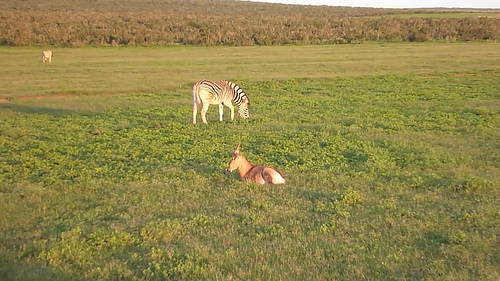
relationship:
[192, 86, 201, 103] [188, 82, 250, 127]
tail on zebra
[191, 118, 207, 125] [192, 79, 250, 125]
feet are on animal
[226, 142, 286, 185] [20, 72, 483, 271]
animal laying in grass field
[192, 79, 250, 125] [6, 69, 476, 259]
animal grazing in field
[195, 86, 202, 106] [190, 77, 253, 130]
tail on zebra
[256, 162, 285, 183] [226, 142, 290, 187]
haunch on antelope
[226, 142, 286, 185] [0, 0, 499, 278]
animal laying in field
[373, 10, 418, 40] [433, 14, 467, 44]
leaves are on trees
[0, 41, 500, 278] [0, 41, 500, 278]
grass field on grass field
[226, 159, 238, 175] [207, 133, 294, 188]
nose on antelope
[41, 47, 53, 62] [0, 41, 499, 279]
animal on grass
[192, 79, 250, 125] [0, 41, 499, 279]
animal on grass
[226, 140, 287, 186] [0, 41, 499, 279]
animal on grass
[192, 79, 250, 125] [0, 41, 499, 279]
animal eating grass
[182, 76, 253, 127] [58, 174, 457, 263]
animal laying on grass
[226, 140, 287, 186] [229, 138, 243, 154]
animal with horns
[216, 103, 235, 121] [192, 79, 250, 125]
feet on animal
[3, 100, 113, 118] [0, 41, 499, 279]
shadow on grass